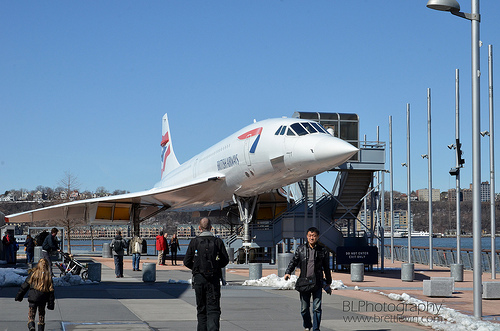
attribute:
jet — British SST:
[2, 109, 358, 257]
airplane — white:
[13, 80, 357, 270]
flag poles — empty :
[363, 44, 495, 279]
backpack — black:
[190, 234, 227, 289]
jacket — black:
[266, 214, 353, 316]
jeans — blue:
[302, 289, 342, 311]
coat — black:
[177, 235, 236, 278]